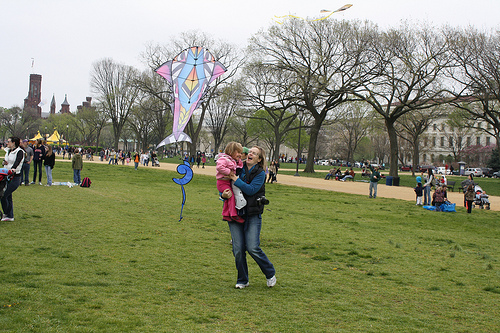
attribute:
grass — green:
[297, 221, 380, 274]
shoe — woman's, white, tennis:
[223, 271, 278, 288]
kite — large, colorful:
[110, 44, 229, 148]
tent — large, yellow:
[40, 122, 73, 162]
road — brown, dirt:
[306, 177, 338, 192]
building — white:
[301, 106, 461, 168]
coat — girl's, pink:
[209, 160, 254, 193]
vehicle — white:
[437, 164, 450, 174]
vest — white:
[224, 176, 248, 211]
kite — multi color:
[150, 23, 226, 152]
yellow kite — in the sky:
[320, 0, 370, 17]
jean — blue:
[212, 213, 282, 293]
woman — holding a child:
[206, 126, 247, 226]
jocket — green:
[66, 132, 87, 179]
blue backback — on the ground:
[415, 197, 458, 220]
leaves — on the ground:
[253, 113, 303, 143]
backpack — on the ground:
[69, 172, 96, 192]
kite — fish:
[148, 36, 228, 143]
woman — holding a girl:
[203, 130, 250, 229]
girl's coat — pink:
[209, 149, 240, 189]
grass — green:
[10, 221, 351, 331]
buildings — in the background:
[4, 55, 112, 137]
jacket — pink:
[204, 155, 236, 207]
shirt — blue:
[234, 152, 283, 283]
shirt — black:
[4, 124, 29, 229]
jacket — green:
[62, 136, 102, 214]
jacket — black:
[39, 121, 79, 260]